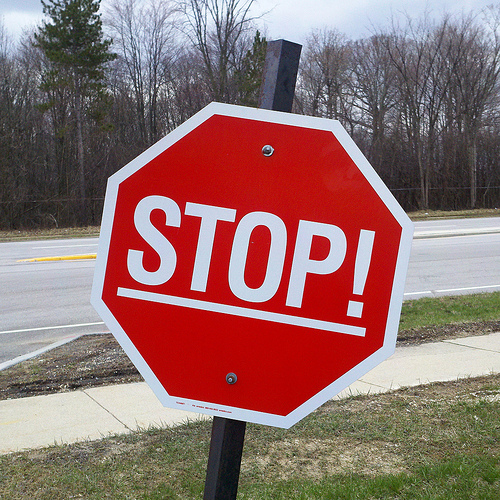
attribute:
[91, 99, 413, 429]
sign — red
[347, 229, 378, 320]
exclamation mark — white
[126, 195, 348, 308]
word — underlined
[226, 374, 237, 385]
pin — grey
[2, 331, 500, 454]
sidewalk — nearby, concrete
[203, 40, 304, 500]
signpost — black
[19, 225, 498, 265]
line — yellow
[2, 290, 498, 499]
grass — cut, dead, green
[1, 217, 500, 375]
road — grey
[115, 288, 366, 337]
line — white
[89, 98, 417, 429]
border — white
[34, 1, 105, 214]
tree — pine, bare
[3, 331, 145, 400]
dirt — wet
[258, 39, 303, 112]
post — rusted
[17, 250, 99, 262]
median — yellow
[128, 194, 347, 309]
lettering — white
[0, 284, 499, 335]
line — white